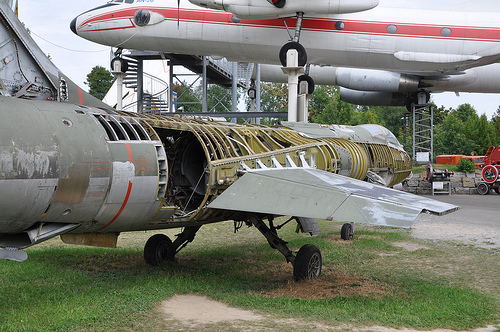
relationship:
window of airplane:
[441, 28, 451, 38] [68, 1, 499, 111]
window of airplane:
[388, 24, 396, 33] [68, 1, 499, 111]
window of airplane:
[334, 20, 347, 30] [68, 1, 499, 111]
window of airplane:
[231, 16, 238, 24] [68, 1, 499, 111]